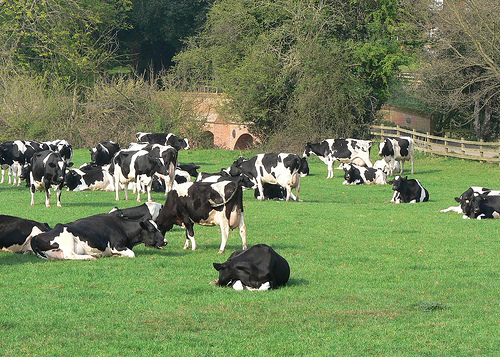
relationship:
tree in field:
[264, 13, 377, 158] [2, 140, 500, 357]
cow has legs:
[152, 170, 250, 257] [179, 211, 206, 264]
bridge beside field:
[369, 122, 500, 163] [2, 140, 500, 357]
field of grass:
[2, 140, 500, 357] [53, 120, 495, 340]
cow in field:
[208, 243, 293, 294] [2, 140, 498, 344]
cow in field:
[138, 180, 249, 255] [2, 140, 498, 344]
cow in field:
[445, 178, 499, 216] [2, 140, 498, 344]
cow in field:
[383, 175, 429, 205] [2, 140, 498, 344]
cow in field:
[377, 138, 417, 177] [2, 140, 498, 344]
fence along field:
[361, 122, 500, 169] [2, 140, 498, 344]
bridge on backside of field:
[369, 120, 485, 162] [8, 62, 498, 349]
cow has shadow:
[208, 243, 293, 294] [278, 275, 310, 287]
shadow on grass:
[278, 275, 310, 287] [5, 142, 499, 350]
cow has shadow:
[138, 180, 249, 255] [196, 242, 306, 249]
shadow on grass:
[196, 242, 306, 249] [5, 142, 499, 350]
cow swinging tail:
[152, 170, 250, 257] [203, 171, 241, 211]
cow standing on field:
[25, 149, 74, 206] [2, 140, 498, 344]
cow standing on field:
[138, 180, 249, 255] [2, 140, 498, 344]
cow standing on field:
[222, 150, 302, 201] [2, 140, 498, 344]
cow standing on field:
[302, 138, 375, 179] [2, 140, 498, 344]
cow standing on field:
[377, 135, 414, 173] [2, 140, 498, 344]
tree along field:
[224, 1, 395, 152] [144, 129, 459, 354]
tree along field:
[68, 61, 205, 156] [144, 129, 459, 354]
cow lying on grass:
[208, 243, 293, 294] [5, 142, 499, 350]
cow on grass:
[208, 243, 293, 294] [5, 142, 499, 350]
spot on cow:
[266, 169, 284, 184] [238, 152, 303, 201]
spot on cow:
[254, 163, 267, 175] [238, 152, 303, 201]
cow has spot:
[238, 152, 303, 201] [266, 169, 284, 184]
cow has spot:
[238, 152, 303, 201] [254, 163, 267, 175]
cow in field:
[383, 175, 429, 205] [48, 92, 463, 310]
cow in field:
[377, 138, 417, 177] [48, 92, 463, 310]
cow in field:
[208, 243, 293, 294] [48, 92, 463, 310]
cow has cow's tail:
[152, 170, 250, 257] [210, 180, 238, 208]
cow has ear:
[193, 229, 328, 299] [210, 258, 226, 272]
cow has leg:
[138, 180, 249, 255] [234, 214, 250, 252]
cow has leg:
[138, 180, 249, 255] [212, 218, 233, 256]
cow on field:
[440, 186, 500, 220] [2, 140, 498, 344]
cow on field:
[386, 173, 428, 205] [2, 140, 498, 344]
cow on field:
[208, 243, 293, 294] [2, 140, 498, 344]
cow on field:
[28, 208, 170, 265] [2, 140, 498, 344]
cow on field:
[300, 136, 385, 176] [2, 140, 498, 344]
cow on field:
[208, 243, 293, 294] [4, 126, 496, 353]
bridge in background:
[156, 86, 437, 151] [3, 3, 483, 164]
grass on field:
[5, 142, 499, 350] [2, 140, 498, 344]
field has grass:
[2, 140, 498, 344] [5, 142, 499, 350]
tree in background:
[218, 28, 397, 148] [3, 3, 483, 164]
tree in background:
[68, 61, 213, 157] [3, 3, 483, 164]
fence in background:
[355, 103, 492, 178] [3, 3, 483, 164]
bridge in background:
[369, 122, 500, 163] [3, 3, 483, 164]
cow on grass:
[208, 243, 293, 294] [37, 290, 475, 355]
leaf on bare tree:
[384, 51, 396, 65] [440, 2, 499, 126]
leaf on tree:
[395, 21, 410, 33] [2, 1, 133, 91]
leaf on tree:
[345, 34, 356, 49] [130, 1, 214, 75]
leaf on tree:
[255, 80, 267, 92] [172, 1, 299, 131]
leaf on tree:
[248, 15, 260, 27] [282, 30, 383, 137]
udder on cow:
[284, 171, 301, 189] [208, 243, 293, 294]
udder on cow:
[348, 152, 368, 167] [387, 168, 432, 203]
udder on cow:
[138, 167, 152, 188] [444, 180, 498, 228]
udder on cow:
[212, 207, 242, 229] [28, 208, 170, 265]